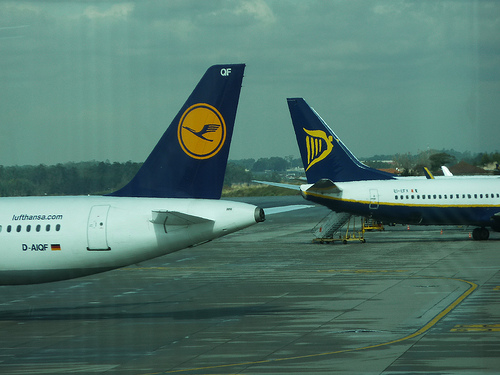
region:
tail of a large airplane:
[73, 57, 273, 275]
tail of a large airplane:
[247, 72, 394, 238]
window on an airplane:
[52, 218, 62, 235]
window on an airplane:
[43, 220, 51, 235]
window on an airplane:
[32, 221, 41, 235]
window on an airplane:
[24, 221, 31, 235]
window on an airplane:
[12, 220, 22, 235]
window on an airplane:
[5, 221, 12, 235]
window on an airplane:
[392, 192, 399, 202]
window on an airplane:
[442, 191, 449, 201]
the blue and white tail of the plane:
[122, 61, 242, 202]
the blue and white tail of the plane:
[286, 93, 388, 183]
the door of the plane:
[84, 205, 115, 255]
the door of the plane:
[368, 186, 378, 208]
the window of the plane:
[6, 223, 11, 232]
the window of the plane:
[15, 223, 21, 232]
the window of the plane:
[24, 224, 31, 231]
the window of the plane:
[35, 224, 40, 232]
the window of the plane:
[44, 223, 51, 231]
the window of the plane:
[54, 221, 61, 233]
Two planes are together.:
[0, 64, 499, 286]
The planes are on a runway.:
[0, 64, 497, 374]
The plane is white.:
[110, 203, 146, 248]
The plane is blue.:
[144, 167, 208, 191]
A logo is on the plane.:
[183, 122, 220, 142]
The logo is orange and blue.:
[176, 101, 228, 159]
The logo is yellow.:
[303, 128, 335, 167]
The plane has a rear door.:
[87, 204, 112, 249]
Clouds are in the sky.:
[190, 5, 276, 29]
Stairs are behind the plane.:
[310, 210, 347, 244]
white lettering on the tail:
[219, 68, 231, 75]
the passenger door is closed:
[85, 205, 111, 248]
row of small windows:
[1, 223, 60, 230]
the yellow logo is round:
[176, 103, 226, 158]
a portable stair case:
[313, 212, 349, 242]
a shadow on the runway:
[7, 308, 348, 320]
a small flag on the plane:
[50, 243, 59, 250]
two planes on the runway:
[1, 63, 498, 284]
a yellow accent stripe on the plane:
[303, 191, 499, 206]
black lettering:
[11, 213, 64, 219]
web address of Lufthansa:
[6, 207, 68, 226]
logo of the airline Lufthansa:
[173, 96, 232, 170]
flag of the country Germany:
[48, 240, 64, 259]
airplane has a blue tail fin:
[106, 55, 246, 197]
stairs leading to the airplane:
[292, 200, 358, 244]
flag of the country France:
[410, 185, 420, 194]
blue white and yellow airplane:
[281, 98, 498, 245]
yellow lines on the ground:
[45, 239, 496, 370]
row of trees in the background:
[6, 152, 499, 194]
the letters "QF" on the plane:
[215, 61, 233, 82]